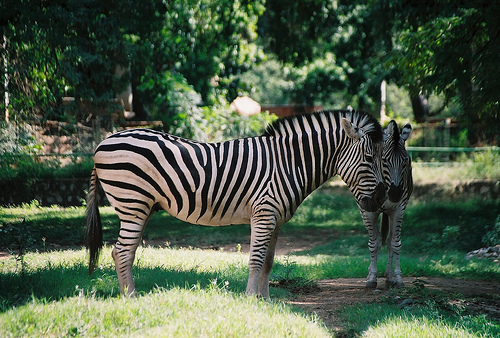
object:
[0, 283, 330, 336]
spot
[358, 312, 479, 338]
spot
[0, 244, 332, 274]
spot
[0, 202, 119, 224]
spot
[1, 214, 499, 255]
shade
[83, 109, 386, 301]
zebra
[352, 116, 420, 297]
zebra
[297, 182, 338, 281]
leg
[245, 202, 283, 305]
leg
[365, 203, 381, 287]
leg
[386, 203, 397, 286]
leg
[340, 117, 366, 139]
ear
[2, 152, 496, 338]
grass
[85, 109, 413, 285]
black stripes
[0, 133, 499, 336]
area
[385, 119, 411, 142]
ears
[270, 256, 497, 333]
shade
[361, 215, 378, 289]
leg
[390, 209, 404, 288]
leg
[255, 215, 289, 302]
leg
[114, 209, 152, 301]
leg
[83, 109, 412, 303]
zebras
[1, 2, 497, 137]
trees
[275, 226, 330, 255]
dirt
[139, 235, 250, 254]
dirt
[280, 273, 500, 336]
dirt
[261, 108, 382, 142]
mane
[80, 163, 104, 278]
tail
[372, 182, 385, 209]
nose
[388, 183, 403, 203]
nose